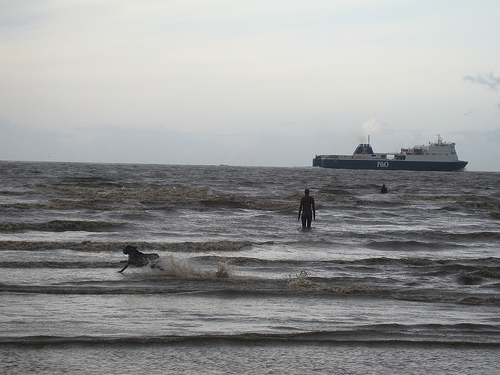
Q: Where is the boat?
A: In the ocean.